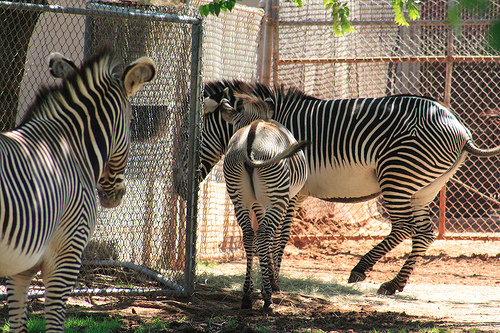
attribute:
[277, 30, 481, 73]
fence — small, metal, big, metallic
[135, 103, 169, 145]
window — small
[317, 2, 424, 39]
leaves — green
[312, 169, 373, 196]
belly — white, bulky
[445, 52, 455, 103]
pole — metal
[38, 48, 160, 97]
ears — big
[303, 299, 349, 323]
ground — brown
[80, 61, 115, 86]
mane — black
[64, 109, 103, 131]
stripes — black, white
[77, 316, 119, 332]
grass — green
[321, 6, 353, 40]
leaf — green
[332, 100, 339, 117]
fur — black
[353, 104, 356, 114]
fur — white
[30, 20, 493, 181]
pen — high